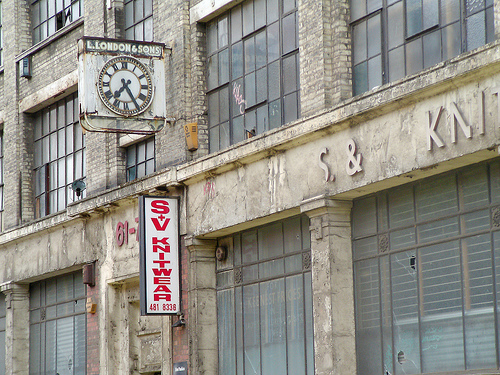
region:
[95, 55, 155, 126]
the clock's hands are black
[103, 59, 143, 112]
the clock's hands are black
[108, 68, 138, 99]
the clock's hands are black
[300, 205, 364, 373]
the column is dusty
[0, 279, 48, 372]
the column is dusty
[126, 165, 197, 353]
a white sign with red letters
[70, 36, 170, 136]
a clock on a building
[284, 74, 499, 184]
Letters on front of building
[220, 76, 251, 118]
red letters on a window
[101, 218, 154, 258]
red numbers on the building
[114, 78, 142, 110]
black hands of the clock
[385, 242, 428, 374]
two holes in a lower window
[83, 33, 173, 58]
white letters above the clock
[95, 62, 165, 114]
roman numberals on the clock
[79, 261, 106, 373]
a strip of red bricks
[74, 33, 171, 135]
an old worn out looking clock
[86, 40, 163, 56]
L. London & Sons sign on the clock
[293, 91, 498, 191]
missing letters on the side of the building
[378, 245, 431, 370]
broken windows from having rocks thrown at them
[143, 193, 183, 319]
a small red and white sign on the side of the building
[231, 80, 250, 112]
graffiti on one of the window panes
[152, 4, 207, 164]
a very dirty section of bricks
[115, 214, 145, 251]
a red sign that says 61-7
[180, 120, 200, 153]
a small yellow container on the side of the building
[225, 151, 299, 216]
patches of cleaner parts on the dirty building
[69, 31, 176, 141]
rusty clock sign on building side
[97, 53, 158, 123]
clock with roman numerals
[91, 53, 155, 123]
clock that reads seven twenty five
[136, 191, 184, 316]
rectangular sign with red lettering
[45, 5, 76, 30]
broken third floor window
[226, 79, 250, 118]
graffiti on second story window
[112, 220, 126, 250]
red 6 on side of building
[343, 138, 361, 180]
faded & on side of building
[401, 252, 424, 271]
broken first floor window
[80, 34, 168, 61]
rusty L.London & Sons sign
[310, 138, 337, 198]
letter S on the building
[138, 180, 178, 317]
sign on the side of a building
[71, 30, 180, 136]
clock attached to side of building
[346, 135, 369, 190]
& sign on the side of building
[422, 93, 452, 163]
Letter K on side of building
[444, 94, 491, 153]
M on the side of a building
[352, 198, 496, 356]
glass windows on the building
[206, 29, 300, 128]
a group of glass windows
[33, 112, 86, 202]
a group of glass windows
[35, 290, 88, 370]
a group of glass windows